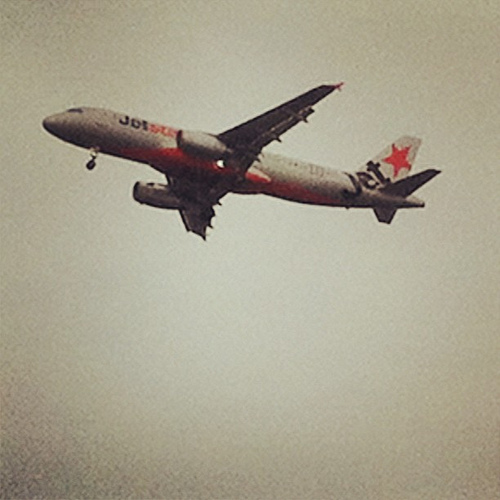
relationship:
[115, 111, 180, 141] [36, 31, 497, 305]
name on plane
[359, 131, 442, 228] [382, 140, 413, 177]
plane tail has a star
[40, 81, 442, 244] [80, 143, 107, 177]
plane has landing gear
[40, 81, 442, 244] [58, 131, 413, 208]
plane has plane's underside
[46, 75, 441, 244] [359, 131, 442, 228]
plane has plane tail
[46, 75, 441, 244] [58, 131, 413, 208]
plane has plane's underside